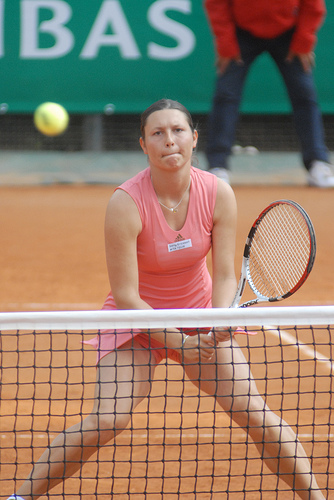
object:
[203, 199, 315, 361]
racket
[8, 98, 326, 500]
player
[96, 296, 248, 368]
bloomers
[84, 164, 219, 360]
clothing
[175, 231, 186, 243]
adidas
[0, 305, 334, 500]
net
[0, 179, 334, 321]
court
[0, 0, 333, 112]
banner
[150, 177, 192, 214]
necklace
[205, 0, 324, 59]
sweater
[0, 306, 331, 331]
top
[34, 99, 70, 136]
ball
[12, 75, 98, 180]
air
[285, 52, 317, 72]
hands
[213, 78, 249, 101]
knees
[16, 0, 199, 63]
letters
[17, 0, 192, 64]
bas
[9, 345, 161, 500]
legs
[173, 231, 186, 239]
symbol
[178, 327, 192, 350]
bracelet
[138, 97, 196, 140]
hair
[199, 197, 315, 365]
tennis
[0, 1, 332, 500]
picture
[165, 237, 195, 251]
nametag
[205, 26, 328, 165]
jeans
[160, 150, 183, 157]
lips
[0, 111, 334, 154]
fence